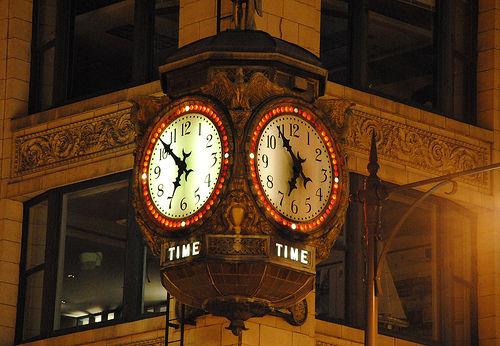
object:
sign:
[164, 240, 201, 261]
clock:
[132, 97, 232, 230]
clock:
[242, 93, 342, 235]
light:
[89, 311, 103, 323]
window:
[56, 171, 139, 327]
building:
[1, 1, 499, 344]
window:
[62, 0, 147, 99]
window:
[360, 0, 451, 111]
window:
[359, 173, 448, 344]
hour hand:
[168, 151, 193, 202]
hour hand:
[286, 151, 308, 195]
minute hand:
[157, 134, 193, 181]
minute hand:
[272, 124, 312, 191]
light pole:
[345, 136, 496, 345]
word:
[167, 239, 203, 260]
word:
[274, 242, 310, 267]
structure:
[130, 29, 350, 337]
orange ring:
[143, 101, 225, 228]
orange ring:
[247, 105, 340, 230]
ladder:
[160, 283, 187, 345]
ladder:
[216, 1, 241, 34]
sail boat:
[373, 244, 408, 333]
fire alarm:
[78, 253, 101, 270]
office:
[20, 182, 168, 340]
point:
[363, 126, 379, 181]